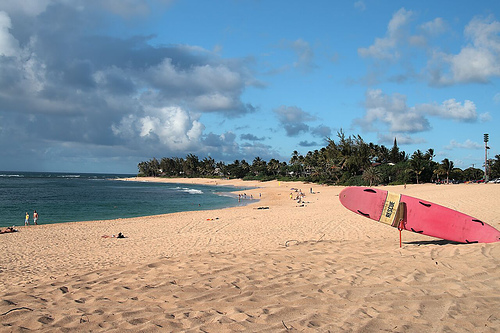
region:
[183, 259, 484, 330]
Sand on the beach.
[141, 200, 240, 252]
Tracks in the sand.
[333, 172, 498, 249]
Surfboard on the beach.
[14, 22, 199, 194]
Clouds in the sky.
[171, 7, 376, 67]
Sky behind the clouds is blue.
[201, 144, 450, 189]
The trees are green.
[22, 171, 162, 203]
The water is blue.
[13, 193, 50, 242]
People next to the water.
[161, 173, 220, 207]
White foam in the water.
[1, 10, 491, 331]
Taken on a beach.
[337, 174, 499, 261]
a surfboard sticking up out of the sand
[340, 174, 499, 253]
the surfboard is pink and yellow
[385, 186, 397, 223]
the writing on the surfboard is black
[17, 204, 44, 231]
2 people are walking on the beach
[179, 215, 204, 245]
some bike tracks in the sand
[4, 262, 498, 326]
many foot prints are in the sand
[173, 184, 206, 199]
the waves are rolling into the shore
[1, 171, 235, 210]
the water is a dark blue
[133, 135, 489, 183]
there are deep green trees are in the background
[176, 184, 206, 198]
the waves have a white froth on top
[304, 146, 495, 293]
a surfboard on the beach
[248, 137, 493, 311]
a red surfboard on the beach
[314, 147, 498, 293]
a surfboard on the sand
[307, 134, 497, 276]
a red surfboard on the sand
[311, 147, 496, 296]
a surfboard on its side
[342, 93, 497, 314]
a red surfboard on its side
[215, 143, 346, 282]
people on the beach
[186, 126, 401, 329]
people on the sand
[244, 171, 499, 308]
a beach with a surfboard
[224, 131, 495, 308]
a bech with a red surfboard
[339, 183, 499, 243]
red surfboard on the beach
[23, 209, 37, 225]
people walking on the beach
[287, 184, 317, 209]
people in the distance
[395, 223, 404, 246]
a red stand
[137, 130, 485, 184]
a stretch of foliage in the distance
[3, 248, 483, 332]
sand on the beach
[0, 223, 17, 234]
person laying on the beach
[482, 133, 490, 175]
a large metal post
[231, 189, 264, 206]
people in the distance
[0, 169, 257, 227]
a section of the ocean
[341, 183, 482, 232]
this is a surfboard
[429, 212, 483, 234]
the board is red in color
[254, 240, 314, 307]
this is the beach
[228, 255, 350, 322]
this is a sand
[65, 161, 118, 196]
this is a water body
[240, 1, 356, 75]
this is the sky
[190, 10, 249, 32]
the sky is blue in color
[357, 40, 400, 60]
these are the clouds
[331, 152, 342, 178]
this is a tree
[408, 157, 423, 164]
the leaves are green in color